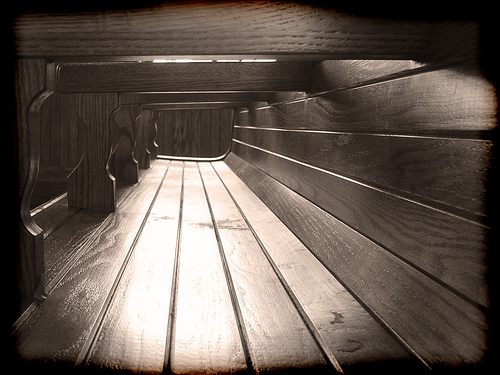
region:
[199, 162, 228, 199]
Dark brown wood grain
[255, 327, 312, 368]
Dark brown wood grain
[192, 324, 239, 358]
Dark brown wood grain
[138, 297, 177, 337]
Dark brown wood grain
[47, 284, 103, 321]
Dark brown wood grain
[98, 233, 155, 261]
Dark brown wood grain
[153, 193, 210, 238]
Dark brown wood grain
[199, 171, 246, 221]
Dark brown wood grain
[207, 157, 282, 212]
Dark brown wood grain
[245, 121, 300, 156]
Dark brown wood grain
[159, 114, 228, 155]
looking through wood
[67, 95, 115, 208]
wood supporting another piece of wood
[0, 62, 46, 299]
wood supporting another piece of wood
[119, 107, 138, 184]
wood supporting another piece of wood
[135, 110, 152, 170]
wood supporting another piece of wood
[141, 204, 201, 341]
the lighting shining through and bouncing on the wood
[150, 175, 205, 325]
light bouncing on the wood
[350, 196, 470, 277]
patterns of the wood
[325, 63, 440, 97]
crevices between the wood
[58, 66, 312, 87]
a horizontal piece of wood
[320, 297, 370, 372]
dent in the wood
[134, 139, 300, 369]
shadow on the wood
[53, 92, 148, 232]
design carved in the wood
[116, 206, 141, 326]
cracks in the wood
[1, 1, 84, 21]
black border on picture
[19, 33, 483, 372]
wood is black and white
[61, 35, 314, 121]
wooden tiles on the ceiling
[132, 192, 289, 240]
carvings in the wood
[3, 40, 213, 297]
wooden object has design in it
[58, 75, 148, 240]
wood pieces are carved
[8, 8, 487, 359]
a structure of wood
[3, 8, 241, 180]
wall of wood on the background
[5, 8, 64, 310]
vertical plank of wood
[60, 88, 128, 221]
vertical plank of wood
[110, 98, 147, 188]
vertical plank of wood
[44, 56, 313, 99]
horizontal plank of wood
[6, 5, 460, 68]
horizontal plank of wood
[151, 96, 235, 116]
horizontal plank of wood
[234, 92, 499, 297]
planks of wood forming a backsit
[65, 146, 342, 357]
planks of wood forming a sit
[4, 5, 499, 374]
Wooden bench with seat dividers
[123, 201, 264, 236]
Large Mark on the wood bench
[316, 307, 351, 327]
Small seal shaped mark on bench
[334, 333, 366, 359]
Small crescent moon shape mark on bench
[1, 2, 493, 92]
horizontal wood planks part of seat divider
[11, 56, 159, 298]
Vertical wood planks part of seat divider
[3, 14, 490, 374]
A bunch of wood planks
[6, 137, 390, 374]
Wood planks laid flat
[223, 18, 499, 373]
Back of bench made out of wood planks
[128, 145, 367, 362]
Glare from the sun